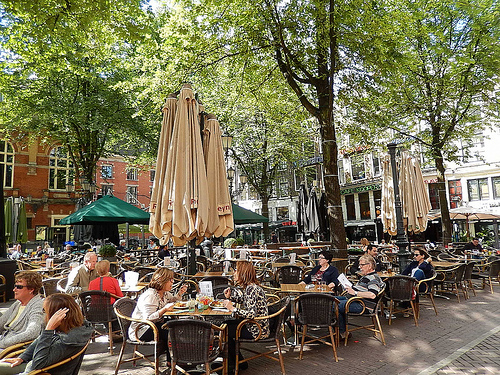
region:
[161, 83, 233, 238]
set of closed umbrellas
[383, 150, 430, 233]
second set of closed umbrellas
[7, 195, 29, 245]
third set of closed umbrellas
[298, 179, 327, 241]
fourth set of closed umbrellas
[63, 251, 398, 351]
square tables with chairs and people sitting at them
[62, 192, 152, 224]
a tent opened up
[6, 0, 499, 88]
a canopy of trees giving shade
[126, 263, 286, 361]
people sitting and chatting and eating outside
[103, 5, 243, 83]
brightness indicates the sun is out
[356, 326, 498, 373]
walkway for people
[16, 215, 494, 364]
several table and chairs are placed outside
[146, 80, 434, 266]
the umbrellas are closed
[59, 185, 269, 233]
small green tents are placed in the back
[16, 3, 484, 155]
trees are in this area as well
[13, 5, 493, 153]
the trees are filled with green leaves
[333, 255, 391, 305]
this man is looking at a menu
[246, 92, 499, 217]
a building can be seen through the trees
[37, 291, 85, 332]
this woman is touching her hair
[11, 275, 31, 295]
this woman is wearing sunglasses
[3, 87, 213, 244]
this building is red in color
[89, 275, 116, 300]
The red shirt the lady is wearing.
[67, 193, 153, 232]
The green canopy on the left.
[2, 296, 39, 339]
The gray sweater that the lady with sunglasses is wearing.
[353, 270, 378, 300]
The stripe shirt the man is wearing.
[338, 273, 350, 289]
The menu that is in the man's hands.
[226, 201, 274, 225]
The green canopy on the right.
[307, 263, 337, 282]
The blue jacket the lady is wearing.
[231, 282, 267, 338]
The animal print shirt the lady is wearing.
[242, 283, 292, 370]
The chair the lady in the animal print shirt is sitting in.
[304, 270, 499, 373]
The brick patio the chairs and tables are on.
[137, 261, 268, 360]
two women sitting at a table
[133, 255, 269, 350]
ladies dining outside at a cafe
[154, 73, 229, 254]
a group of closed umbrellas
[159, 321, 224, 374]
black wicker chair at a table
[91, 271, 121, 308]
red shirt on a person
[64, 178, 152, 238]
green triangular canopy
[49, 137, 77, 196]
window on a brick building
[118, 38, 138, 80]
green leaves on a tree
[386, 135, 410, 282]
metal pole ina dining area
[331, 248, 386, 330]
man reading at a table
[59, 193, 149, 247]
green tent under tree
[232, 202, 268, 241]
green tent under trees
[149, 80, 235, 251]
beige umbrellas folded down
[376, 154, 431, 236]
beige umbrellas folded down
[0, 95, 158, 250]
brick building with windows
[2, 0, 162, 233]
tree in middle of cafe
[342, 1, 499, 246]
tree in cafe area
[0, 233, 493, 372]
people sitting in cafe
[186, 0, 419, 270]
tree growing in cafe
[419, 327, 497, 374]
brick path beside cafe